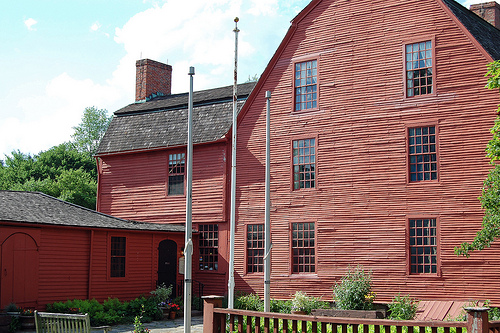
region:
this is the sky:
[21, 40, 76, 64]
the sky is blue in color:
[49, 34, 76, 59]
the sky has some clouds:
[126, 25, 217, 47]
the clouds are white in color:
[127, 20, 154, 43]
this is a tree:
[33, 151, 79, 188]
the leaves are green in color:
[39, 155, 75, 187]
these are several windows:
[285, 32, 445, 275]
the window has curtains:
[408, 47, 429, 65]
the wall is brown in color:
[331, 133, 379, 230]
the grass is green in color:
[276, 320, 285, 332]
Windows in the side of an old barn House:
[397, 35, 447, 100]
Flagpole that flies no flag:
[223, 16, 245, 331]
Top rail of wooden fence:
[210, 308, 468, 325]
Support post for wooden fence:
[195, 285, 223, 332]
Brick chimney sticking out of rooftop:
[130, 56, 173, 109]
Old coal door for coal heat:
[410, 294, 481, 327]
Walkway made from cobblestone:
[116, 312, 201, 330]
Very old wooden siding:
[324, 138, 394, 189]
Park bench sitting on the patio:
[22, 305, 95, 332]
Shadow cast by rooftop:
[237, 127, 277, 189]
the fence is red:
[229, 311, 246, 317]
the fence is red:
[262, 310, 273, 326]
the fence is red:
[250, 305, 260, 316]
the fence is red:
[237, 318, 248, 321]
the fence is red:
[243, 314, 250, 316]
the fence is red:
[241, 318, 255, 329]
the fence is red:
[230, 300, 240, 331]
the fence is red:
[232, 311, 246, 323]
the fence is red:
[226, 314, 241, 321]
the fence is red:
[234, 313, 248, 327]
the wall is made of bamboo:
[313, 75, 415, 298]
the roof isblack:
[99, 102, 270, 162]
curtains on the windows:
[400, 46, 437, 97]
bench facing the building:
[30, 297, 106, 327]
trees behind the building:
[8, 102, 145, 252]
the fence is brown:
[199, 297, 460, 331]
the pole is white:
[215, 18, 260, 315]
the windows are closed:
[270, 52, 495, 312]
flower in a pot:
[163, 297, 185, 331]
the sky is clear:
[6, 15, 151, 140]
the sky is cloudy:
[0, 1, 310, 194]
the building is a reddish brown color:
[2, 1, 497, 304]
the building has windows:
[135, 33, 460, 287]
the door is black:
[129, 216, 211, 317]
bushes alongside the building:
[31, 278, 199, 326]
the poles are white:
[127, 15, 302, 328]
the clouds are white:
[74, 0, 306, 106]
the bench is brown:
[18, 298, 122, 331]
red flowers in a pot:
[161, 296, 189, 328]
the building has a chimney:
[102, 40, 258, 168]